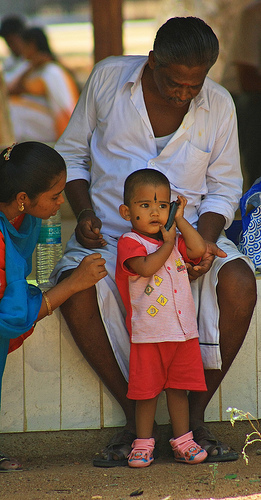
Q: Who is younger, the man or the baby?
A: The baby is younger than the man.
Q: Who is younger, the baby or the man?
A: The baby is younger than the man.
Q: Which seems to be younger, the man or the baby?
A: The baby is younger than the man.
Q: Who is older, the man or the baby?
A: The man is older than the baby.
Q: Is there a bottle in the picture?
A: Yes, there is a bottle.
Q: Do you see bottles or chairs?
A: Yes, there is a bottle.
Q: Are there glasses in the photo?
A: No, there are no glasses.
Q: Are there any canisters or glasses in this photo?
A: No, there are no glasses or canisters.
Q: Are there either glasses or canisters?
A: No, there are no glasses or canisters.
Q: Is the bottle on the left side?
A: Yes, the bottle is on the left of the image.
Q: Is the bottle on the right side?
A: No, the bottle is on the left of the image.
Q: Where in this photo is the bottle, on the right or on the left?
A: The bottle is on the left of the image.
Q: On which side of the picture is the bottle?
A: The bottle is on the left of the image.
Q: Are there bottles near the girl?
A: Yes, there is a bottle near the girl.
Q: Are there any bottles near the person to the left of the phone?
A: Yes, there is a bottle near the girl.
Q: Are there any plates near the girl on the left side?
A: No, there is a bottle near the girl.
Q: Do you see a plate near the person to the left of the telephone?
A: No, there is a bottle near the girl.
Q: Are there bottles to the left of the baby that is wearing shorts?
A: Yes, there is a bottle to the left of the baby.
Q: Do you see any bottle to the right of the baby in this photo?
A: No, the bottle is to the left of the baby.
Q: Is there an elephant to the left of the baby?
A: No, there is a bottle to the left of the baby.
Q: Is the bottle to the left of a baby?
A: Yes, the bottle is to the left of a baby.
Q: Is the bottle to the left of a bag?
A: No, the bottle is to the left of a baby.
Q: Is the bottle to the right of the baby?
A: No, the bottle is to the left of the baby.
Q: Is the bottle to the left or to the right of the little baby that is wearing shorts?
A: The bottle is to the left of the baby.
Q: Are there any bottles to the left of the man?
A: Yes, there is a bottle to the left of the man.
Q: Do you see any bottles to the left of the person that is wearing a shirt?
A: Yes, there is a bottle to the left of the man.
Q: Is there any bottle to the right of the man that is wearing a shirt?
A: No, the bottle is to the left of the man.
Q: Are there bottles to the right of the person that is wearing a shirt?
A: No, the bottle is to the left of the man.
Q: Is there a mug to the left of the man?
A: No, there is a bottle to the left of the man.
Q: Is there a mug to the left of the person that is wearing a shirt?
A: No, there is a bottle to the left of the man.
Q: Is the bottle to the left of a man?
A: Yes, the bottle is to the left of a man.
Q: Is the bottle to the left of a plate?
A: No, the bottle is to the left of a man.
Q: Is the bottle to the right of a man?
A: No, the bottle is to the left of a man.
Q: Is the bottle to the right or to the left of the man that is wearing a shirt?
A: The bottle is to the left of the man.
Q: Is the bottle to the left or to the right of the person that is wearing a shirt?
A: The bottle is to the left of the man.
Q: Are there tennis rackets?
A: No, there are no tennis rackets.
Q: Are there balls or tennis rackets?
A: No, there are no tennis rackets or balls.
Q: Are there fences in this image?
A: No, there are no fences.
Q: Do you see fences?
A: No, there are no fences.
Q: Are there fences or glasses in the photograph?
A: No, there are no fences or glasses.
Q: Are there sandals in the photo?
A: Yes, there are sandals.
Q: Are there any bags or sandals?
A: Yes, there are sandals.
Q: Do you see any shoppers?
A: No, there are no shoppers.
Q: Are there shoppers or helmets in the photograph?
A: No, there are no shoppers or helmets.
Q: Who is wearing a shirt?
A: The man is wearing a shirt.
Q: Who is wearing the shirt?
A: The man is wearing a shirt.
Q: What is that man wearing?
A: The man is wearing a shirt.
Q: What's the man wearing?
A: The man is wearing a shirt.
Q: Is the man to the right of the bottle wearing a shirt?
A: Yes, the man is wearing a shirt.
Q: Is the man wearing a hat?
A: No, the man is wearing a shirt.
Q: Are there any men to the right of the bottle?
A: Yes, there is a man to the right of the bottle.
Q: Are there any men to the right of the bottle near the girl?
A: Yes, there is a man to the right of the bottle.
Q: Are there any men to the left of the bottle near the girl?
A: No, the man is to the right of the bottle.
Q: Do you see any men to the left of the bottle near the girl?
A: No, the man is to the right of the bottle.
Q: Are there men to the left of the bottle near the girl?
A: No, the man is to the right of the bottle.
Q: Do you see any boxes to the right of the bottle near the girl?
A: No, there is a man to the right of the bottle.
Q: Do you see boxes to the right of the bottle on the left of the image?
A: No, there is a man to the right of the bottle.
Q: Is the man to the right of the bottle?
A: Yes, the man is to the right of the bottle.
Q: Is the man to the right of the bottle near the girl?
A: Yes, the man is to the right of the bottle.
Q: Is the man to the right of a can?
A: No, the man is to the right of the bottle.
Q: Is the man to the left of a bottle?
A: No, the man is to the right of a bottle.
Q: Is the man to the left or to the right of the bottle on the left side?
A: The man is to the right of the bottle.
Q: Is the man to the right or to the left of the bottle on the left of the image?
A: The man is to the right of the bottle.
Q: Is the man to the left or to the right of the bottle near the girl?
A: The man is to the right of the bottle.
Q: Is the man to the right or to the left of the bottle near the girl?
A: The man is to the right of the bottle.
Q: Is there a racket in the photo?
A: No, there are no rackets.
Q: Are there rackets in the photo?
A: No, there are no rackets.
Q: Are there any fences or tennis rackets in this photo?
A: No, there are no tennis rackets or fences.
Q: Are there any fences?
A: No, there are no fences.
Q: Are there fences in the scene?
A: No, there are no fences.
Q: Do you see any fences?
A: No, there are no fences.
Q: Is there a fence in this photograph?
A: No, there are no fences.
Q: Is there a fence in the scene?
A: No, there are no fences.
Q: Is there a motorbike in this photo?
A: No, there are no motorcycles.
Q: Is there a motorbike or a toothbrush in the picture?
A: No, there are no motorcycles or toothbrushes.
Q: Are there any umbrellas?
A: No, there are no umbrellas.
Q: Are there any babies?
A: Yes, there is a baby.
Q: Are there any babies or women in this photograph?
A: Yes, there is a baby.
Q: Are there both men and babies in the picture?
A: Yes, there are both a baby and a man.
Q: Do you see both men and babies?
A: Yes, there are both a baby and a man.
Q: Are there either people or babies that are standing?
A: Yes, the baby is standing.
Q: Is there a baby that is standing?
A: Yes, there is a baby that is standing.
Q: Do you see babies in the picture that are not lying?
A: Yes, there is a baby that is standing .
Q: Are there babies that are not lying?
A: Yes, there is a baby that is standing.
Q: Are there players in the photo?
A: No, there are no players.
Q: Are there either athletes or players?
A: No, there are no players or athletes.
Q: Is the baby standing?
A: Yes, the baby is standing.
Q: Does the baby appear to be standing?
A: Yes, the baby is standing.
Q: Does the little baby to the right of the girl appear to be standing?
A: Yes, the baby is standing.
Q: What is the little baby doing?
A: The baby is standing.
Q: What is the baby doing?
A: The baby is standing.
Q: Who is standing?
A: The baby is standing.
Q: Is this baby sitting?
A: No, the baby is standing.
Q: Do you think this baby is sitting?
A: No, the baby is standing.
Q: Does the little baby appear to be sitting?
A: No, the baby is standing.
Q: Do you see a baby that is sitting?
A: No, there is a baby but he is standing.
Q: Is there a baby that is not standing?
A: No, there is a baby but he is standing.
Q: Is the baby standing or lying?
A: The baby is standing.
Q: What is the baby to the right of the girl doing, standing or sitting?
A: The baby is standing.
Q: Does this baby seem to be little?
A: Yes, the baby is little.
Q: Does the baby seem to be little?
A: Yes, the baby is little.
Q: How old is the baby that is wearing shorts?
A: The baby is little.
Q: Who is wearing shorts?
A: The baby is wearing shorts.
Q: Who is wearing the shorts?
A: The baby is wearing shorts.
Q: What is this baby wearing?
A: The baby is wearing shorts.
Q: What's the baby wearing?
A: The baby is wearing shorts.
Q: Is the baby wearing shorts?
A: Yes, the baby is wearing shorts.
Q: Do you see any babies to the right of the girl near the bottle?
A: Yes, there is a baby to the right of the girl.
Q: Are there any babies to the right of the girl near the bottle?
A: Yes, there is a baby to the right of the girl.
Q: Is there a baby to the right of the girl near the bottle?
A: Yes, there is a baby to the right of the girl.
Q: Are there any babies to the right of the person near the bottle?
A: Yes, there is a baby to the right of the girl.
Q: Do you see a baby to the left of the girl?
A: No, the baby is to the right of the girl.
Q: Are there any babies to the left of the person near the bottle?
A: No, the baby is to the right of the girl.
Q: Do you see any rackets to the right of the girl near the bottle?
A: No, there is a baby to the right of the girl.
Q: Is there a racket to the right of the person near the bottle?
A: No, there is a baby to the right of the girl.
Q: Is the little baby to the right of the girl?
A: Yes, the baby is to the right of the girl.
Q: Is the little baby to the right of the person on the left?
A: Yes, the baby is to the right of the girl.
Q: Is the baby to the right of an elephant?
A: No, the baby is to the right of the girl.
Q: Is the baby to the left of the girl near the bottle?
A: No, the baby is to the right of the girl.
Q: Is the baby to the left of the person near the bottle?
A: No, the baby is to the right of the girl.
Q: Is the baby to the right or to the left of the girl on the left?
A: The baby is to the right of the girl.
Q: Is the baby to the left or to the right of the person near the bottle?
A: The baby is to the right of the girl.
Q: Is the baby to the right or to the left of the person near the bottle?
A: The baby is to the right of the girl.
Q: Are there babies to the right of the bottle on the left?
A: Yes, there is a baby to the right of the bottle.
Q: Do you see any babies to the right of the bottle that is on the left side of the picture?
A: Yes, there is a baby to the right of the bottle.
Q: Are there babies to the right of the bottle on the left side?
A: Yes, there is a baby to the right of the bottle.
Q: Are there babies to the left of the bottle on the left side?
A: No, the baby is to the right of the bottle.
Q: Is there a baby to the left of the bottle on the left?
A: No, the baby is to the right of the bottle.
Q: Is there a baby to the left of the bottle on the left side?
A: No, the baby is to the right of the bottle.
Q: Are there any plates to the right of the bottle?
A: No, there is a baby to the right of the bottle.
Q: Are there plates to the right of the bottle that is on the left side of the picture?
A: No, there is a baby to the right of the bottle.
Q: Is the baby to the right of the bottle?
A: Yes, the baby is to the right of the bottle.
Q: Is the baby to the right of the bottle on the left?
A: Yes, the baby is to the right of the bottle.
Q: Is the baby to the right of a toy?
A: No, the baby is to the right of the bottle.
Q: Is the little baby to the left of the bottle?
A: No, the baby is to the right of the bottle.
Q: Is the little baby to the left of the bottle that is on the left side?
A: No, the baby is to the right of the bottle.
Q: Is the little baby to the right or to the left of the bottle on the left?
A: The baby is to the right of the bottle.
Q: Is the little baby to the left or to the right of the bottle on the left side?
A: The baby is to the right of the bottle.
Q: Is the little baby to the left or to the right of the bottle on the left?
A: The baby is to the right of the bottle.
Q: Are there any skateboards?
A: No, there are no skateboards.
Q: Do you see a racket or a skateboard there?
A: No, there are no skateboards or rackets.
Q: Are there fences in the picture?
A: No, there are no fences.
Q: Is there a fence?
A: No, there are no fences.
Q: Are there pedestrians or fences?
A: No, there are no fences or pedestrians.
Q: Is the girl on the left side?
A: Yes, the girl is on the left of the image.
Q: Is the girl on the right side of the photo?
A: No, the girl is on the left of the image.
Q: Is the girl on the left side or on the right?
A: The girl is on the left of the image.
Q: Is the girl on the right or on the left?
A: The girl is on the left of the image.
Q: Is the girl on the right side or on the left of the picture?
A: The girl is on the left of the image.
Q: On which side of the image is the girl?
A: The girl is on the left of the image.